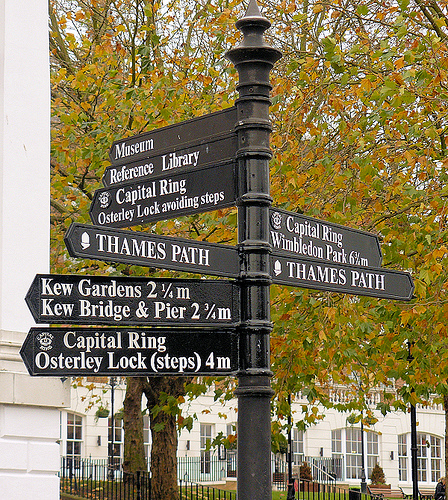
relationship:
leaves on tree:
[327, 88, 375, 162] [283, 12, 434, 400]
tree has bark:
[98, 156, 187, 492] [157, 447, 174, 471]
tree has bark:
[283, 12, 434, 400] [157, 447, 174, 471]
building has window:
[72, 373, 447, 491] [65, 411, 81, 469]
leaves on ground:
[76, 480, 112, 498] [79, 493, 369, 500]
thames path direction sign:
[275, 255, 410, 295] [69, 225, 237, 270]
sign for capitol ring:
[261, 206, 386, 264] [285, 221, 351, 244]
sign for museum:
[106, 110, 248, 142] [119, 140, 157, 146]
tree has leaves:
[283, 12, 434, 400] [327, 88, 375, 162]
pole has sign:
[227, 22, 274, 495] [261, 206, 386, 264]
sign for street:
[261, 206, 386, 264] [111, 496, 447, 499]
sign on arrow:
[106, 110, 248, 142] [108, 134, 161, 166]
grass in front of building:
[185, 480, 233, 492] [72, 373, 447, 491]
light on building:
[381, 445, 395, 463] [72, 373, 447, 491]